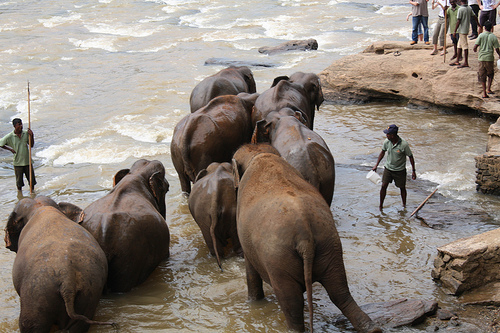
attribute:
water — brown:
[95, 78, 157, 126]